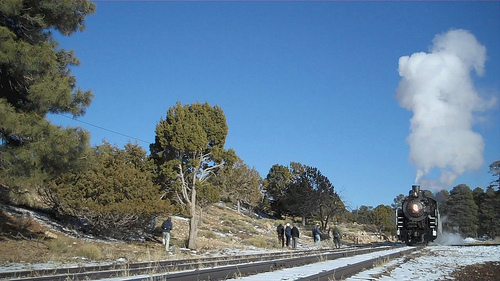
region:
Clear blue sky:
[112, 34, 243, 76]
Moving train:
[389, 180, 444, 247]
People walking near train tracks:
[266, 214, 330, 262]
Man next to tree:
[144, 96, 231, 251]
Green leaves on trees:
[1, 104, 156, 211]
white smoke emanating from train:
[373, 56, 498, 125]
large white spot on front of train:
[395, 191, 440, 236]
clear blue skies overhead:
[177, 32, 304, 84]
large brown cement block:
[150, 200, 219, 235]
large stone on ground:
[34, 227, 79, 245]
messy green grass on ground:
[20, 232, 123, 256]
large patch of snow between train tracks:
[278, 250, 427, 270]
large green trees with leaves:
[129, 87, 251, 215]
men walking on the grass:
[264, 213, 305, 248]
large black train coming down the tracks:
[391, 183, 463, 248]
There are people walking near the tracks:
[23, 32, 498, 264]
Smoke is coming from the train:
[303, 31, 480, 278]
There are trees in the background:
[7, 6, 366, 272]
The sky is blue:
[86, 13, 436, 203]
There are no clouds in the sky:
[78, 9, 459, 179]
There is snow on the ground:
[40, 189, 482, 277]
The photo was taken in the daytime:
[27, 11, 457, 274]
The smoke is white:
[372, 56, 498, 228]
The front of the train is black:
[333, 174, 461, 255]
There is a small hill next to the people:
[66, 109, 354, 252]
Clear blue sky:
[220, 11, 385, 91]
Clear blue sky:
[238, 80, 392, 157]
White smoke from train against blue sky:
[386, 21, 491, 178]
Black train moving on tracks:
[394, 185, 445, 247]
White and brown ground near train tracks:
[425, 246, 497, 273]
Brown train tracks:
[198, 249, 407, 279]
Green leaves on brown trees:
[8, 14, 116, 204]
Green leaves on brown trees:
[96, 99, 256, 248]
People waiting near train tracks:
[262, 202, 347, 253]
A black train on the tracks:
[382, 170, 456, 251]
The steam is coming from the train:
[370, 23, 494, 190]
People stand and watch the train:
[257, 213, 354, 253]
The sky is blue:
[154, 6, 368, 91]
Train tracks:
[211, 246, 426, 280]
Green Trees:
[2, 1, 83, 209]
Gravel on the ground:
[430, 243, 492, 279]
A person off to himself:
[149, 209, 179, 253]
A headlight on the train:
[411, 201, 421, 214]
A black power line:
[63, 111, 156, 143]